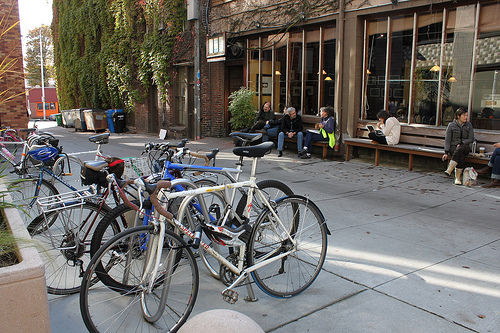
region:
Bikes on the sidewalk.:
[40, 114, 292, 331]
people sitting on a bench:
[191, 84, 433, 184]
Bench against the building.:
[316, 57, 479, 192]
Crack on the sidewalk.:
[330, 172, 439, 314]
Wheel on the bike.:
[214, 191, 373, 303]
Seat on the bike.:
[90, 114, 123, 159]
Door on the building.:
[169, 39, 269, 111]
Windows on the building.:
[243, 12, 414, 152]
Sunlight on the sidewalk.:
[358, 217, 435, 297]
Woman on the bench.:
[360, 102, 419, 163]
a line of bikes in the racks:
[3, 123, 333, 332]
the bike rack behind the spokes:
[134, 239, 180, 321]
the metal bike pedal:
[223, 284, 240, 308]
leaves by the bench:
[320, 154, 422, 209]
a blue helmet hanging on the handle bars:
[25, 143, 65, 163]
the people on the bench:
[252, 99, 336, 154]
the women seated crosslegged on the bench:
[359, 109, 407, 154]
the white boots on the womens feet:
[445, 160, 465, 184]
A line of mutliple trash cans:
[51, 104, 133, 131]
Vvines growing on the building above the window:
[203, 0, 336, 37]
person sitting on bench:
[438, 103, 475, 195]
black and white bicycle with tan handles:
[77, 138, 340, 331]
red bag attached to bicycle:
[76, 151, 126, 186]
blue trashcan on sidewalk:
[99, 103, 127, 138]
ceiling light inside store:
[424, 46, 442, 76]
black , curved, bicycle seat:
[228, 135, 282, 163]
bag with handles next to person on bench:
[461, 161, 478, 190]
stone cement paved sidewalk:
[29, 120, 498, 331]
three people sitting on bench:
[246, 95, 340, 163]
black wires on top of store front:
[214, 6, 344, 53]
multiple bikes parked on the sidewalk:
[0, 128, 328, 328]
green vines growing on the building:
[51, 1, 185, 113]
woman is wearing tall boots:
[446, 158, 463, 182]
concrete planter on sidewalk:
[0, 181, 48, 331]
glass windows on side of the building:
[238, 4, 498, 130]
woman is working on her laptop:
[366, 110, 402, 145]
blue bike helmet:
[24, 145, 59, 160]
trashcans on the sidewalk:
[57, 107, 124, 130]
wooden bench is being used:
[351, 120, 499, 178]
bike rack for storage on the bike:
[37, 189, 89, 255]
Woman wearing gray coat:
[439, 105, 472, 184]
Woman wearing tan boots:
[437, 105, 476, 185]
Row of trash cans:
[51, 105, 128, 131]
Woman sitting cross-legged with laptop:
[365, 106, 402, 148]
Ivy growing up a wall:
[51, 3, 172, 103]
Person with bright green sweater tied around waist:
[315, 104, 338, 154]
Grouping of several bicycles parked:
[1, 133, 326, 332]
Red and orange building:
[26, 87, 59, 123]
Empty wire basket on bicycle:
[120, 153, 150, 180]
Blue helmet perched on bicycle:
[23, 142, 62, 169]